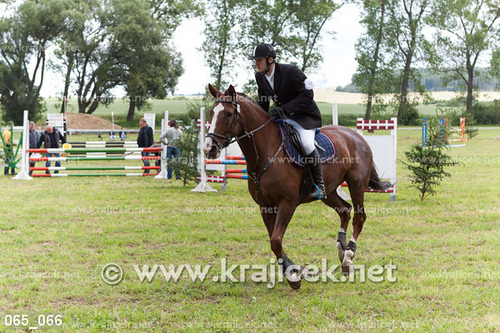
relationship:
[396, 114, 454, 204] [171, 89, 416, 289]
tree on right side of horse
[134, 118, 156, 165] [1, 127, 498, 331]
man standing in grass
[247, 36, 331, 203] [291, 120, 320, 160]
man wearing pants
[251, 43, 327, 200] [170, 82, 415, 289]
man riding horse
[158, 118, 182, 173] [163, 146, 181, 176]
person wearing jeans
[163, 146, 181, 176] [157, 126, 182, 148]
jeans and sweatshirt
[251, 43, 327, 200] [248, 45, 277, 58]
man wearing helmet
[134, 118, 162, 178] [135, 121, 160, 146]
man wears jacket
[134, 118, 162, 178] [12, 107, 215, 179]
man behind fence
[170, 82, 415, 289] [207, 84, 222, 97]
horse has ear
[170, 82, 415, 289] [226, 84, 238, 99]
horse has ear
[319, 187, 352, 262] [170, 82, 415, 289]
leg of horse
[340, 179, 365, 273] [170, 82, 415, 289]
leg of horse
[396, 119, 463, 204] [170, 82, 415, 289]
tree behind horse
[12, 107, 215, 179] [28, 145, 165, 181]
fence has poles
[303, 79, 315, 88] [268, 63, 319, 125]
patch on jacket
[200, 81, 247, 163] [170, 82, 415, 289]
head of horse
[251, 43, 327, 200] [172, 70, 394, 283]
man riding a horse